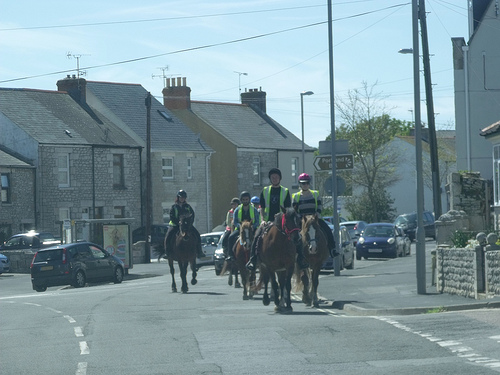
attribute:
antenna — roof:
[229, 65, 249, 92]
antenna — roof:
[148, 61, 182, 86]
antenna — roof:
[59, 41, 89, 76]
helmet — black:
[262, 166, 285, 182]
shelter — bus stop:
[62, 214, 139, 281]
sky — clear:
[1, 0, 498, 148]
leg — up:
[187, 265, 203, 287]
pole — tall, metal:
[410, 2, 431, 297]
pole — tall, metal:
[323, 2, 344, 271]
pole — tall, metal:
[299, 93, 306, 175]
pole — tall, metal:
[142, 102, 154, 264]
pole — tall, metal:
[420, 4, 447, 226]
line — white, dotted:
[5, 297, 92, 373]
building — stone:
[1, 87, 151, 284]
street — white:
[141, 282, 259, 358]